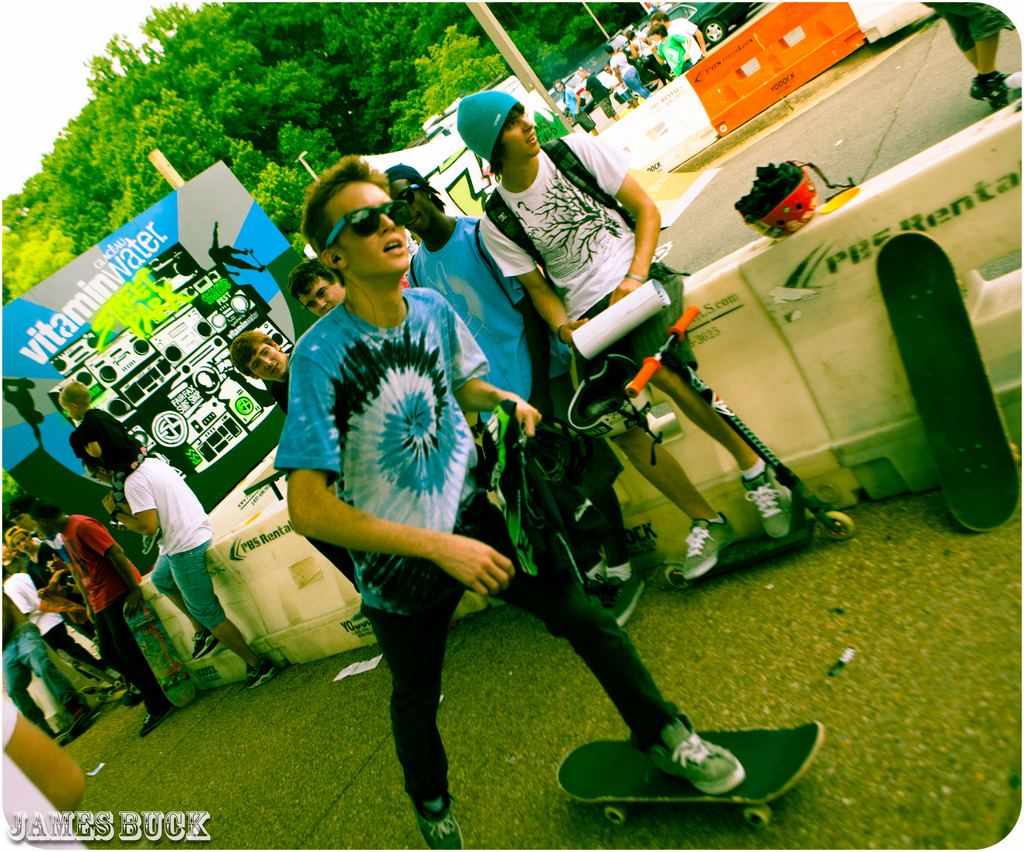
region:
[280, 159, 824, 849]
a guy is skating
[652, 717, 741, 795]
white and green shoe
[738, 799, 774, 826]
the wheel is white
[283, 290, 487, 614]
a tie dyed shirt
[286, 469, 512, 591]
arm of a guy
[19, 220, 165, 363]
the text is white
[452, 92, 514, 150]
the beanie is blue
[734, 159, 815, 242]
black and red helmet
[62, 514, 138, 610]
the shirt is red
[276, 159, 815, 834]
A person on a skate board.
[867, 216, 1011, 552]
A skate board against a wall.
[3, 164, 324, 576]
A large sign on wooden poles.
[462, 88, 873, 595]
A person on a kick and go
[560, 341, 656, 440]
A black and white helmet.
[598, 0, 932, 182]
A orange and white divider.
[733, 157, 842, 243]
A red and black helmet.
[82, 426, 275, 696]
A person sitting on a divider.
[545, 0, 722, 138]
A group of people standing around.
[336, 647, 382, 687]
A piece of white paper on the ground.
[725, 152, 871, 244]
red and black helmet upside-down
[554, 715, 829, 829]
skateboard with one foot on it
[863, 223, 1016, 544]
skateboard standing on end by the barrier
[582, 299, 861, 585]
scooter with red handles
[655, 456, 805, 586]
pair of green sneakers on a scooter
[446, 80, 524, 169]
turquoise stocking cap on a male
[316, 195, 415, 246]
sunglasses being worn by person with one foot on skateboard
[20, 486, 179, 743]
person wearing a red shirt and black pants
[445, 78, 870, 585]
male with two feet on a scooter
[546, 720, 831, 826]
Skateboard under foot.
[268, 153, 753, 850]
Boy riding skate board.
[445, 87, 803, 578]
Boy standing on scooter.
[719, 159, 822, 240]
Helmet above leaning skateboard.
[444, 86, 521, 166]
Hat boy is wearing.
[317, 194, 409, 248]
Sunglasses on boy's face.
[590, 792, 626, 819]
Rear wheel under skateboard.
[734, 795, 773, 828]
Front wheel under skateboard.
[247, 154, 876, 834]
a boy with one foot on a skateboard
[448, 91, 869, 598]
a teenager with two feet on a scooter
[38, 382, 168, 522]
a small child on the shoulders of a man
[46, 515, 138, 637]
a red and black t-shirt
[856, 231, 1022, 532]
a skateboard propped against the barrier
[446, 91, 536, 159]
a light blue hat on his head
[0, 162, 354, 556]
a sign with several boom boxes on it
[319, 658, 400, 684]
a white piece of paper on the ground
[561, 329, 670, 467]
a white helmet in his hand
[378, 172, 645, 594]
person sitting on the white wall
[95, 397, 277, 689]
person sitting on the white wall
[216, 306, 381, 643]
person sitting on the white wall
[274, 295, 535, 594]
blue white and black tie dye shirt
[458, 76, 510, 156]
blue knit cap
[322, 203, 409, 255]
black and blue sunglasses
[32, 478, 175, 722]
young man wearing red shirt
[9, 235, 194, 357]
white lettering on blue background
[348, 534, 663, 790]
black jeans the skateboarder is wearing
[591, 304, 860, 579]
scooter with red handles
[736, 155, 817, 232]
red helmet on the wall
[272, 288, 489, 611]
a tie dyed t-shirt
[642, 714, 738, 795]
a green athletic shoe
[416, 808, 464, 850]
a green athletic shoe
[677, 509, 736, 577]
a green athletic shoe